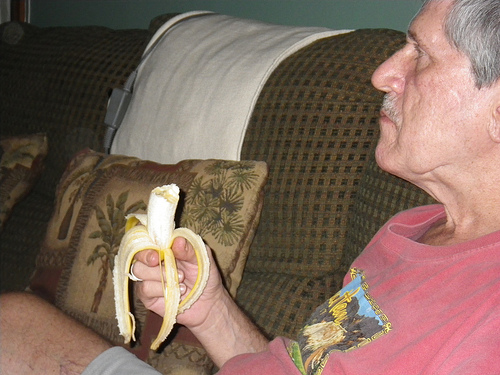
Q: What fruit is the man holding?
A: Banana.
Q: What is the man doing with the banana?
A: Eating it.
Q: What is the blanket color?
A: White.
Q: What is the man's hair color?
A: Gray.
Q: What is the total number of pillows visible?
A: 2.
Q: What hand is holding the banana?
A: Right.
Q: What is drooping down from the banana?
A: Peel.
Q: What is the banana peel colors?
A: Yellow and white.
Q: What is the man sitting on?
A: Couch.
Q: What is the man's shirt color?
A: Pink.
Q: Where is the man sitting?
A: On a couch.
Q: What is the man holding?
A: A banana.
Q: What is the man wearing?
A: A t-shirt.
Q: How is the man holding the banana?
A: By the right arm.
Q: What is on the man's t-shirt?
A: A picture.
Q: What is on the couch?
A: An electric blanket.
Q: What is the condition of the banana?
A: Ripe.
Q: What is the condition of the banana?
A: Peeled.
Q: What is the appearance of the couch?
A: Checkered.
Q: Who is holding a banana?
A: The man sitting on the couch.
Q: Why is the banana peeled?
A: So the man can eat it.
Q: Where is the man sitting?
A: On the couch.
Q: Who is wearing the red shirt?
A: The man eating a banana.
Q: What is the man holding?
A: Banana.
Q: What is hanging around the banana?
A: Banana peel.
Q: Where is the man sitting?
A: Couch.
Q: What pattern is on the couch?
A: Squares.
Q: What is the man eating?
A: Banana.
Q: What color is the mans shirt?
A: Red.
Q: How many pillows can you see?
A: Two.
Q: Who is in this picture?
A: A man.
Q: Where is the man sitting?
A: A couch.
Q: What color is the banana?
A: Yellow.